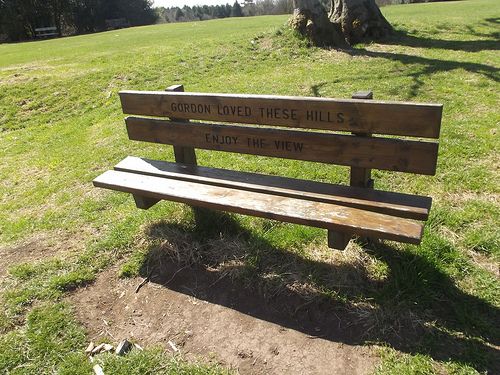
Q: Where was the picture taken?
A: It was taken at the park.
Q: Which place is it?
A: It is a park.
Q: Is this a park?
A: Yes, it is a park.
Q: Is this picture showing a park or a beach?
A: It is showing a park.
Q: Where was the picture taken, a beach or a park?
A: It was taken at a park.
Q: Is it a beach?
A: No, it is a park.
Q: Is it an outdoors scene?
A: Yes, it is outdoors.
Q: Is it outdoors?
A: Yes, it is outdoors.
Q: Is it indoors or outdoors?
A: It is outdoors.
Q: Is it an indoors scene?
A: No, it is outdoors.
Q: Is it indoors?
A: No, it is outdoors.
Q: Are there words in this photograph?
A: Yes, there are words.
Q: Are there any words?
A: Yes, there are words.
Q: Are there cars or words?
A: Yes, there are words.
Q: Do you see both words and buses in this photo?
A: No, there are words but no buses.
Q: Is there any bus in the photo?
A: No, there are no buses.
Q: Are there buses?
A: No, there are no buses.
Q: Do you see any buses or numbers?
A: No, there are no buses or numbers.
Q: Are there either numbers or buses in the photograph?
A: No, there are no buses or numbers.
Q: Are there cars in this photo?
A: No, there are no cars.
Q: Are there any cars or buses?
A: No, there are no cars or buses.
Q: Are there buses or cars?
A: No, there are no cars or buses.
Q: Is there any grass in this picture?
A: Yes, there is grass.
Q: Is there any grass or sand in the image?
A: Yes, there is grass.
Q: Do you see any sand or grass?
A: Yes, there is grass.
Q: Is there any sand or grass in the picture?
A: Yes, there is grass.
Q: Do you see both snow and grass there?
A: No, there is grass but no snow.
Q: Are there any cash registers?
A: No, there are no cash registers.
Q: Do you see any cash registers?
A: No, there are no cash registers.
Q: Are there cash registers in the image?
A: No, there are no cash registers.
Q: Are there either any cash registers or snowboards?
A: No, there are no cash registers or snowboards.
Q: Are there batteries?
A: No, there are no batteries.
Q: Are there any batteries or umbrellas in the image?
A: No, there are no batteries or umbrellas.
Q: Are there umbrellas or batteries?
A: No, there are no batteries or umbrellas.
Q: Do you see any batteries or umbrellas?
A: No, there are no batteries or umbrellas.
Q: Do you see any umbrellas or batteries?
A: No, there are no batteries or umbrellas.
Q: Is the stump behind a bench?
A: Yes, the stump is behind a bench.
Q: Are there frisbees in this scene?
A: No, there are no frisbees.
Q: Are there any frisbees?
A: No, there are no frisbees.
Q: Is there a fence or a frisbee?
A: No, there are no frisbees or fences.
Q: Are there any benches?
A: Yes, there is a bench.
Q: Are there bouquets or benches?
A: Yes, there is a bench.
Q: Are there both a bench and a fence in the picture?
A: No, there is a bench but no fences.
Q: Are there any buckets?
A: No, there are no buckets.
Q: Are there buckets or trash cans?
A: No, there are no buckets or trash cans.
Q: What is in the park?
A: The bench is in the park.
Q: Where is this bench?
A: The bench is in the park.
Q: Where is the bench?
A: The bench is in the park.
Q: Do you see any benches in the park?
A: Yes, there is a bench in the park.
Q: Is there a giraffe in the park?
A: No, there is a bench in the park.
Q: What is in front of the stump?
A: The bench is in front of the stump.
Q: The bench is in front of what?
A: The bench is in front of the stump.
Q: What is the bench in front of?
A: The bench is in front of the stump.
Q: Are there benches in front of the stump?
A: Yes, there is a bench in front of the stump.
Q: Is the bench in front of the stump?
A: Yes, the bench is in front of the stump.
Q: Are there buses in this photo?
A: No, there are no buses.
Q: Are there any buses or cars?
A: No, there are no buses or cars.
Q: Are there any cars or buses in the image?
A: No, there are no buses or cars.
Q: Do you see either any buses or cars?
A: No, there are no buses or cars.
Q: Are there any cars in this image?
A: No, there are no cars.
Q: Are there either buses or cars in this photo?
A: No, there are no cars or buses.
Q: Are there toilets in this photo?
A: No, there are no toilets.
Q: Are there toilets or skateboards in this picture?
A: No, there are no toilets or skateboards.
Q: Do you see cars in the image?
A: No, there are no cars.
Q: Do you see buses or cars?
A: No, there are no cars or buses.